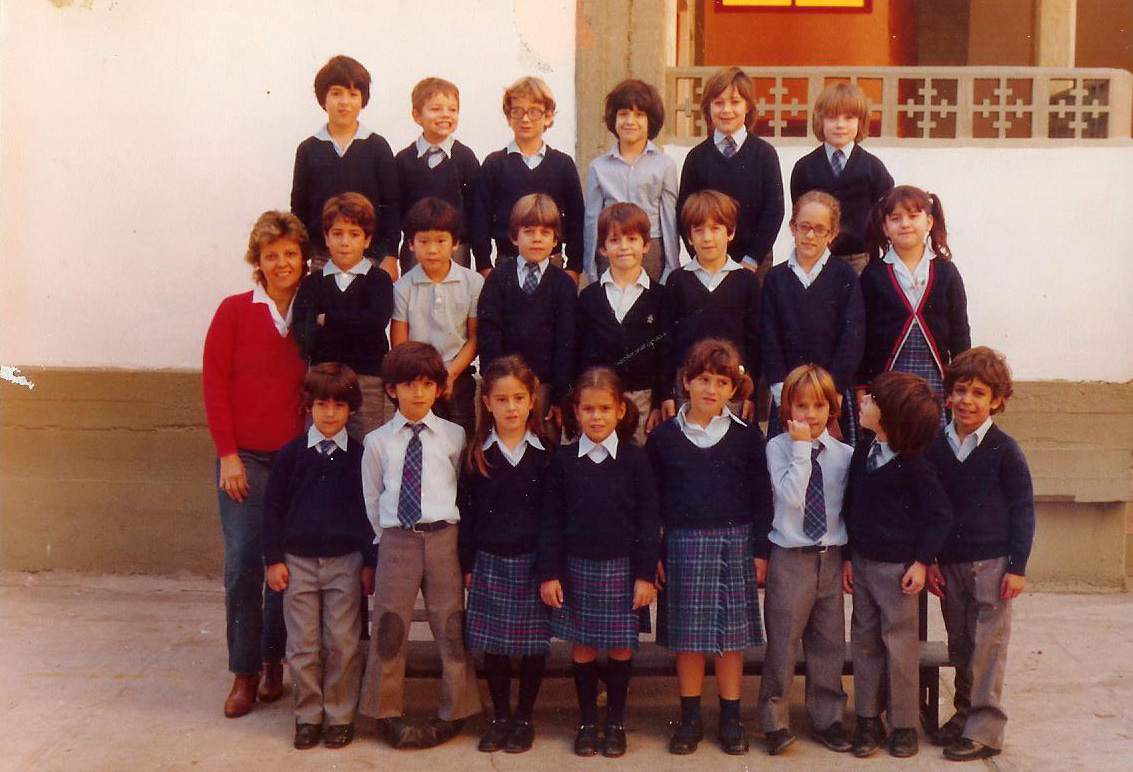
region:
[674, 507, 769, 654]
blue and red plaid skirt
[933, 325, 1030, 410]
boy's bushy brown hair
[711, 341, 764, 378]
barette in girl's hair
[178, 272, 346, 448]
woman wearing long sleeve red sweater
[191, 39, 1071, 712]
children standing in front of building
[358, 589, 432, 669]
patch on boy's pants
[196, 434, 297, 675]
pair of blue jeans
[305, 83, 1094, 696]
a group of people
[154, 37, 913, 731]
a group of kids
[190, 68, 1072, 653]
a group of childers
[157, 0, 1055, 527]
a group of child hood pic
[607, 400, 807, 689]
a girl wearing uniform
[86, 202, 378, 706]
a girl wearing jacket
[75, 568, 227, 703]
a view of floor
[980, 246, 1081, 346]
a view of wall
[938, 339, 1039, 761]
boy wearing uniform pants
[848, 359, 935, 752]
boy wearing blue sweater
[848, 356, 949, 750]
boy wearing uniform pants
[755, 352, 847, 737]
boy wearing neck tie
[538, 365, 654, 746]
girl wearing a sweater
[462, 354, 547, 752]
girl wearing blue sweater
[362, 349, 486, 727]
boy wearing a neck tie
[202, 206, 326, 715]
Woman wearing a red shirt and blue pants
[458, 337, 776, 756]
Three girls with plaid skirts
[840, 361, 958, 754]
Small boy looking behind him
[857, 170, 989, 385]
Girl with pigtails wearing sweater and shirt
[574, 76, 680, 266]
Brown haired boy with dress shirt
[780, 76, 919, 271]
Blonde haired boy with sweater and tie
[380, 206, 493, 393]
Boy with short sleeved shirt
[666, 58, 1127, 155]
Tan wall with railing with blocks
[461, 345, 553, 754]
a little girl posing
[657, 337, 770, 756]
a little girl posing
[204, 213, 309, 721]
the class teacher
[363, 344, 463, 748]
a little boy posing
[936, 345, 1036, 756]
a little boy posing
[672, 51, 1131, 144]
a balcony behind kids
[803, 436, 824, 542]
a tie on a little boy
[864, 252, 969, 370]
a cardigan sweater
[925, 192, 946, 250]
a ponytail on a little girl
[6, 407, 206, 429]
a crack in a wall